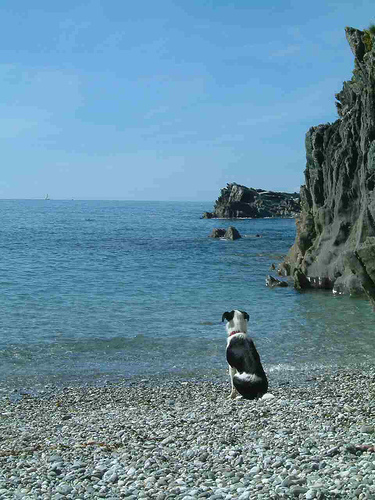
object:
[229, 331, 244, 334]
collar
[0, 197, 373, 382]
sea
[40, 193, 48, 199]
boat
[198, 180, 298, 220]
formation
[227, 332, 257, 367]
fur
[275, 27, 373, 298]
cliff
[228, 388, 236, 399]
paw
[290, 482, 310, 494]
rocks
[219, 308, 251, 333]
head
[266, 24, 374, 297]
cliff-face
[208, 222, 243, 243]
rock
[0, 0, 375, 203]
sky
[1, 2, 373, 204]
clouds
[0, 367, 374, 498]
beach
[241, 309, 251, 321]
ear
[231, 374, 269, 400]
tail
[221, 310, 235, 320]
ear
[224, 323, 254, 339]
neck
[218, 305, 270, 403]
dog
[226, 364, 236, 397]
front leg